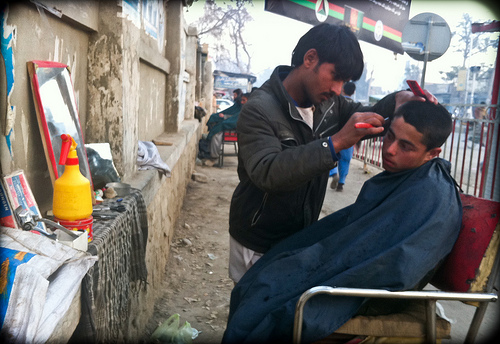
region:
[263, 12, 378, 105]
head of the man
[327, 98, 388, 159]
hand of the man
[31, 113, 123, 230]
red and yellow bottle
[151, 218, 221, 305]
rocks on the ground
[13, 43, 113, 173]
mirror next to wall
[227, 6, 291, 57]
sky above the land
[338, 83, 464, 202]
head of the kid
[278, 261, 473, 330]
arm of the chair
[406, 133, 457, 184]
ear of the kid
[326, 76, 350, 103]
nose on the man's face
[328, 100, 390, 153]
item in man's hand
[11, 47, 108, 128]
object next to bottle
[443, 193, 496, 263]
red back of the chair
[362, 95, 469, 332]
a boy sitting outside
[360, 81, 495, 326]
a boy sitting in a chair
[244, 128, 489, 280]
a boy wearing a robe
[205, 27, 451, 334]
a man cutting hair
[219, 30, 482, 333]
a man cutting hair outside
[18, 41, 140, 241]
a mirror on a wall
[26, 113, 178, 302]
a spray bottle outside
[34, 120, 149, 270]
red and yellow spray bottle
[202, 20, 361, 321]
a man wearing a jacket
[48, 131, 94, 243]
a yellow and red spray bottle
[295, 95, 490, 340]
a man sitting in a chair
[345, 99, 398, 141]
a man holding scissors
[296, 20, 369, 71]
a man with black hair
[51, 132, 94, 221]
Yellow and red water spray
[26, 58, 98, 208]
Mirror has red frame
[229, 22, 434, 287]
barber cuts hair of boy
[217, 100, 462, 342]
boy gets hair cut by barber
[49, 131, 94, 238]
spray bottle is red and yellow